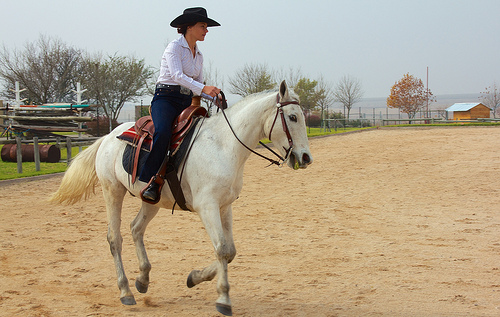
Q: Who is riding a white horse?
A: A woman.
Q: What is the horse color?
A: Whitre.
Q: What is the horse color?
A: White.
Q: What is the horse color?
A: White.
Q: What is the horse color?
A: White.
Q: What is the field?
A: Dirt.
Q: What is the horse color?
A: White.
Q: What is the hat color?
A: Black.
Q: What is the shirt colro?
A: White.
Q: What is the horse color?
A: White.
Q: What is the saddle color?
A: Brown.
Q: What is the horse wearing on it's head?
A: Reins.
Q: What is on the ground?
A: Sand.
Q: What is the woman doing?
A: Riding a horse.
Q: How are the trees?
A: Bare.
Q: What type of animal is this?
A: Horse.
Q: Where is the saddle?
A: On the horse's back.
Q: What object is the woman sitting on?
A: Saddle.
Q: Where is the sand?
A: On the ground.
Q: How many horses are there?
A: One.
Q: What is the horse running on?
A: Dirt.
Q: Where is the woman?
A: On the horse.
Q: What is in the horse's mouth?
A: A bit.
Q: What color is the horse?
A: White.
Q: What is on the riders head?
A: Cowboy hat.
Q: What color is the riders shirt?
A: White.